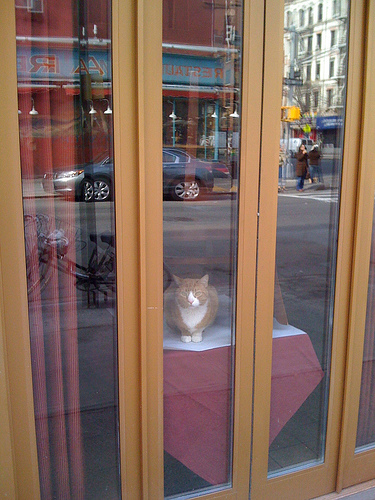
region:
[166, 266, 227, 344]
a cat in a window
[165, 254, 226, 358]
a yellow and white cat in a window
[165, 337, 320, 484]
a red table cloth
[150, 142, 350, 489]
a double glass window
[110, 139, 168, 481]
the fram around window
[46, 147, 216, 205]
a reflection of a car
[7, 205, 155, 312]
a reflection of a bike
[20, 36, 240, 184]
a reflections of a store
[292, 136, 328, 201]
a reflection of people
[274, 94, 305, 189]
a reflections of a street light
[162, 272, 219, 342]
A cat looking outside.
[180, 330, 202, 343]
White front legs of a cat.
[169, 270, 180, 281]
Right ear of a cat.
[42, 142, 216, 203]
A reflection of a car in the window.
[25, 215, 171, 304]
A reflection of a bicycle.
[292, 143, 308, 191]
A reflection of a person.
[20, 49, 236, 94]
A reflection of a store sign.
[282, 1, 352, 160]
A reflection of a building.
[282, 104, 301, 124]
A reflection of a traffic light.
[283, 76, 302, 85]
A reflection of a street sign.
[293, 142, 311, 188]
a person standing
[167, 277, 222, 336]
a cat laying down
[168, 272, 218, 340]
the cat is orange and white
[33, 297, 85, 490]
the curtains are red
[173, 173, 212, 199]
the back tire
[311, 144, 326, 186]
a person standing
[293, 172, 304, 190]
blue jeans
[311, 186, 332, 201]
a cross walk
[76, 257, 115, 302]
a bike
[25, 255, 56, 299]
tire of the bike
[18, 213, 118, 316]
reflection in a window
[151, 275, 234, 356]
orange and white cat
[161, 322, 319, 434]
red and white tablecloth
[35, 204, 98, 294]
white towel in bike basket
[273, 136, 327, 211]
person wearing brown jacket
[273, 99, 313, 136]
small yellow sign on street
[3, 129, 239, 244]
silver car parked on road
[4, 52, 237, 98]
red letters on blue background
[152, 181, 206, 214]
black tire with silver rim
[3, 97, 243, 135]
white lights on ceiling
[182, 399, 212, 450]
red table cloth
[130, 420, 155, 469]
wooden frame on door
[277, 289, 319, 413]
tall piece of glass in window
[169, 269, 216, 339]
cat on table top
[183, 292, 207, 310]
white color on cat's face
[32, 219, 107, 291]
bike's reflection in glass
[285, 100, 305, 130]
yellow traffic light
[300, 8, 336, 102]
white apartment building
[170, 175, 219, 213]
silver rim on gray car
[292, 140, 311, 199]
woman standing on the street